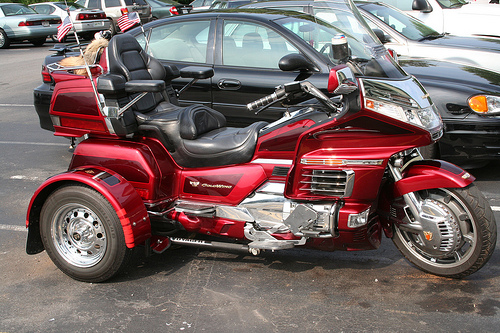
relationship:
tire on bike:
[39, 183, 127, 281] [23, 36, 498, 284]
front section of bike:
[302, 65, 498, 280] [23, 36, 498, 284]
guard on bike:
[314, 2, 444, 137] [23, 36, 498, 284]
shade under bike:
[101, 241, 400, 292] [23, 36, 498, 284]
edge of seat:
[137, 116, 258, 165] [104, 33, 269, 170]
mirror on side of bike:
[328, 63, 358, 95] [23, 36, 498, 284]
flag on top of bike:
[56, 12, 76, 42] [23, 36, 498, 284]